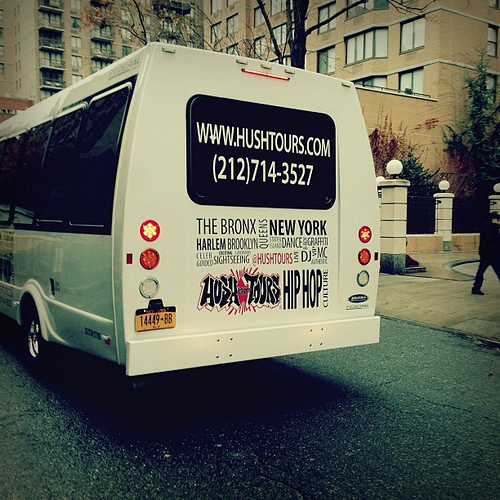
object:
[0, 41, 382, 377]
bus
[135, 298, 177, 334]
tag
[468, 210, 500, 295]
person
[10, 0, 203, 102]
building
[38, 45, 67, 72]
balconies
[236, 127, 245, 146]
letters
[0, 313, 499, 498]
road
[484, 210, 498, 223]
hat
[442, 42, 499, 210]
tree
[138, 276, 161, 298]
light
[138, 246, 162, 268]
light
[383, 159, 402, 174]
lights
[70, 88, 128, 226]
window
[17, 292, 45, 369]
wheel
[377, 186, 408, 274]
post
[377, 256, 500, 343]
sidewalk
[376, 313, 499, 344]
edge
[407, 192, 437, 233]
fence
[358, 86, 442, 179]
wall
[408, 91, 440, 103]
edge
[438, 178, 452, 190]
light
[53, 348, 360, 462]
shadow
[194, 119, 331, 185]
advertisement